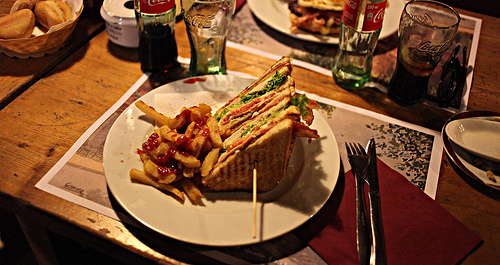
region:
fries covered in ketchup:
[131, 94, 218, 205]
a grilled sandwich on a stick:
[211, 61, 295, 233]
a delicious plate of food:
[108, 65, 332, 243]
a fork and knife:
[348, 130, 389, 264]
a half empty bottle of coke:
[137, 0, 183, 77]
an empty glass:
[188, 0, 245, 80]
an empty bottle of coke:
[335, 0, 391, 87]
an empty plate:
[442, 114, 497, 196]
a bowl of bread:
[3, 2, 88, 62]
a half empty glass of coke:
[386, 0, 462, 102]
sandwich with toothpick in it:
[216, 98, 306, 212]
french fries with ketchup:
[148, 109, 216, 197]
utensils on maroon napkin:
[341, 145, 406, 260]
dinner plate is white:
[161, 190, 218, 232]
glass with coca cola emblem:
[403, 21, 445, 123]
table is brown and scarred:
[11, 93, 105, 148]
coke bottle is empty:
[323, 36, 378, 102]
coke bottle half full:
[136, 40, 191, 78]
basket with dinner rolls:
[5, 17, 58, 59]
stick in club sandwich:
[248, 170, 263, 252]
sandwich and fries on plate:
[92, 58, 342, 260]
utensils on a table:
[333, 125, 398, 263]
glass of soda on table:
[396, 8, 467, 115]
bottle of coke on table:
[332, 2, 398, 97]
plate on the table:
[443, 102, 494, 184]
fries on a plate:
[131, 95, 200, 204]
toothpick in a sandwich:
[241, 167, 270, 244]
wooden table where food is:
[9, 82, 78, 130]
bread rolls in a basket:
[3, 0, 90, 67]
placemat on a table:
[369, 100, 440, 182]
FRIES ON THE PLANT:
[142, 106, 164, 118]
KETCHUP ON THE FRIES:
[161, 173, 168, 178]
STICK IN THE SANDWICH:
[252, 183, 258, 230]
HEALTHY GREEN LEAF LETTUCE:
[290, 98, 305, 101]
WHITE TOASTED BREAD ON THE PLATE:
[271, 151, 289, 162]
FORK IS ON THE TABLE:
[345, 140, 357, 164]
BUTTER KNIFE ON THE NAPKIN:
[366, 146, 377, 212]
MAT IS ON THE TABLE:
[52, 158, 74, 188]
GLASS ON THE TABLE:
[202, 16, 217, 56]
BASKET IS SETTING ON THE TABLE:
[26, 40, 52, 51]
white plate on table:
[106, 109, 322, 236]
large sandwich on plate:
[201, 70, 284, 222]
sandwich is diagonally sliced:
[202, 76, 282, 221]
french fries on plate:
[151, 56, 204, 205]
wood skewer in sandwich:
[231, 171, 293, 249]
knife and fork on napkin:
[347, 149, 399, 249]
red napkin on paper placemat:
[335, 162, 405, 262]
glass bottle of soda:
[317, 0, 379, 87]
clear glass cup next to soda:
[395, 9, 446, 129]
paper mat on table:
[36, 116, 445, 186]